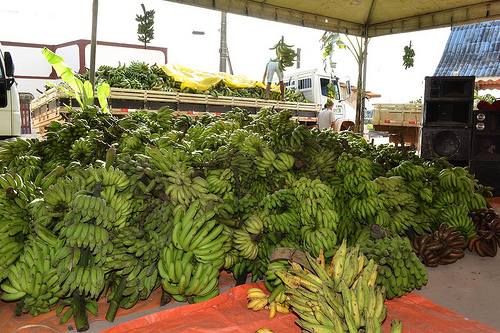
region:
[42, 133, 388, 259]
Banana are green color.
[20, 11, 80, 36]
Sky is white color.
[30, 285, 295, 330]
Banana is on orange sheet.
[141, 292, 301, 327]
Orange sheet is spread on the ground.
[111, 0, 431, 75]
Bunch of banana is hanging.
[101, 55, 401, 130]
One truck is standing.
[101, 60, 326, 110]
Truck is loaded with bunch of banana.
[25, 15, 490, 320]
Day time picture.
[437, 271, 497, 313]
Ground is brown color.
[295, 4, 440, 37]
Shed is yellow color.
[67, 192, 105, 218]
a bunch of bananas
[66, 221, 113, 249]
a bunch of bananas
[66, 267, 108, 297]
a bunch of bananas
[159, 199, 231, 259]
a bunch of bananas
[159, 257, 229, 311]
a bunch of bananas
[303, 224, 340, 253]
a bunch of bananas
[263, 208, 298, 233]
a bunch of bananas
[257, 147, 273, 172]
a bunch of bananas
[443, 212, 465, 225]
a bunch of bananas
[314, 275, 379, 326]
a bunch of bananas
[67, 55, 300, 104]
Handles of bananas on top of truck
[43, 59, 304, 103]
Bananas are green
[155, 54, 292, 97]
Cover is yellow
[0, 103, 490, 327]
Handles of bananas on floor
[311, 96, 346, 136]
Person near the truck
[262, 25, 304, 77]
Handle of banana hanging from awning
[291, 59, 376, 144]
Front of truck is white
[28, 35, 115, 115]
Leaves of banana tree are green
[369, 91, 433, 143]
Truck load with bananas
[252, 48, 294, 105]
Person stand on border of truck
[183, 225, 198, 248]
a green banana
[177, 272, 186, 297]
a green banana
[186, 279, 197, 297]
a green banana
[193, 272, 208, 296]
a green banana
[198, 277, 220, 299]
a green banana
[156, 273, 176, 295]
a green banana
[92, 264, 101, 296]
a green banana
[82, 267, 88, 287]
a green banana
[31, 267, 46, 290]
a green banana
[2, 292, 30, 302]
a green banana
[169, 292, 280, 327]
the mats are orange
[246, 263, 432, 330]
bananas on the mat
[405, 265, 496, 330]
mat is on the ground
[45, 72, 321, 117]
bananas on the truck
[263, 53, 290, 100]
person is on truck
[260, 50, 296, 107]
the person is bent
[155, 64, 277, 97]
yellow cover is on bananas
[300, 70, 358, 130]
the truck is white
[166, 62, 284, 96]
the cover is yellow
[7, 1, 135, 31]
the sky is gray